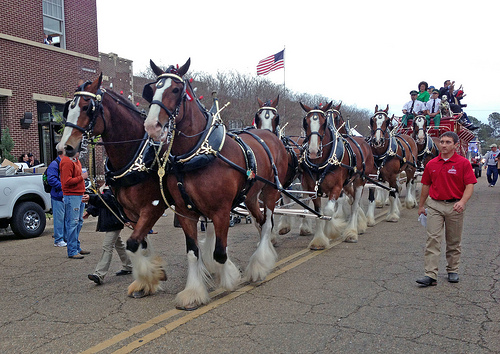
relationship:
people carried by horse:
[405, 80, 478, 132] [145, 57, 300, 311]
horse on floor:
[145, 57, 300, 311] [0, 161, 499, 354]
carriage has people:
[398, 118, 458, 138] [405, 80, 478, 132]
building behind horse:
[0, 2, 137, 183] [145, 57, 300, 311]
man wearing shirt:
[418, 130, 478, 283] [421, 152, 478, 202]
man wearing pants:
[418, 130, 478, 283] [425, 198, 463, 277]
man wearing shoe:
[418, 130, 478, 283] [415, 271, 438, 286]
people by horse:
[43, 148, 91, 259] [145, 57, 300, 311]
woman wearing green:
[417, 79, 432, 104] [419, 92, 430, 103]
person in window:
[43, 32, 55, 45] [43, 0, 68, 52]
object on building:
[19, 112, 34, 129] [0, 2, 137, 183]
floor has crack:
[0, 161, 499, 354] [479, 250, 499, 354]